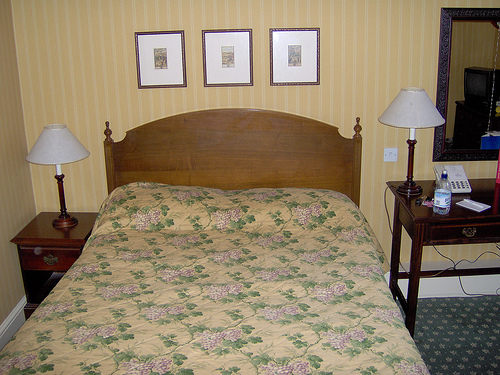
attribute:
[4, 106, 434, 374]
bed — queen size, wood, wooden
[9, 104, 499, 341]
wood — brown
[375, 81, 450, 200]
lamp — brown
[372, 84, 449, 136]
shade — white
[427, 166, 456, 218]
bottle — plastic, clear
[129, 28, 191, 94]
picture — side by side, framed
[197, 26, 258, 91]
picture — side by side, framed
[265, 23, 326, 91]
picture — side by side, framed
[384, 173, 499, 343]
table — dark, wooden, brown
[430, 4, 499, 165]
mirror — large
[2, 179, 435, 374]
cover — floral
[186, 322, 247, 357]
flower — pink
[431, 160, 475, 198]
telephone — white, landline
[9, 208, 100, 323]
night stand — wood, brown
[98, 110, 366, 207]
headboard — wooden, brown, wood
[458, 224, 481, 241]
handle — metal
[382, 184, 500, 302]
cord — entangled, long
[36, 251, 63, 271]
handle — metal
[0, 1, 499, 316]
wallpaper — striped